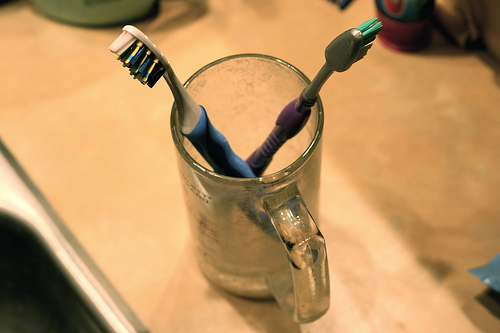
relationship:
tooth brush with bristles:
[241, 17, 383, 177] [346, 12, 389, 39]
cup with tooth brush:
[169, 53, 332, 323] [241, 17, 383, 177]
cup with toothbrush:
[169, 53, 332, 323] [104, 24, 253, 179]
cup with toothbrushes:
[169, 53, 332, 323] [121, 30, 401, 142]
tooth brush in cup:
[241, 17, 383, 177] [169, 53, 332, 323]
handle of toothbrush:
[230, 88, 318, 173] [250, 12, 386, 164]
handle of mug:
[262, 182, 331, 324] [150, 40, 361, 324]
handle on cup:
[262, 182, 331, 324] [169, 53, 332, 323]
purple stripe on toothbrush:
[260, 130, 279, 155] [323, 12, 380, 81]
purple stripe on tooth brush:
[260, 130, 279, 155] [241, 17, 383, 177]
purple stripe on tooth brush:
[267, 128, 283, 145] [241, 17, 383, 177]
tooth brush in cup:
[244, 17, 381, 175] [149, 47, 339, 324]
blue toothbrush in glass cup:
[107, 22, 282, 238] [160, 59, 354, 329]